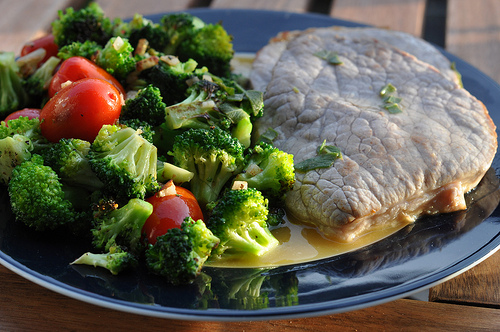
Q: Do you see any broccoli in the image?
A: Yes, there is broccoli.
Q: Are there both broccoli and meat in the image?
A: Yes, there are both broccoli and meat.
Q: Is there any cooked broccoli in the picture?
A: Yes, there is cooked broccoli.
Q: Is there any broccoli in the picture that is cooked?
A: Yes, there is broccoli that is cooked.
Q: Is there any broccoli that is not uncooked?
A: Yes, there is cooked broccoli.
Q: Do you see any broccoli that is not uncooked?
A: Yes, there is cooked broccoli.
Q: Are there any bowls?
A: No, there are no bowls.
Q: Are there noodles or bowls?
A: No, there are no bowls or noodles.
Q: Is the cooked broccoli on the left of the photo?
A: Yes, the broccoli is on the left of the image.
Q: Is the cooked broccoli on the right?
A: No, the broccoli is on the left of the image.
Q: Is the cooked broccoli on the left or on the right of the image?
A: The broccoli is on the left of the image.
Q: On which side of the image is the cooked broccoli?
A: The broccoli is on the left of the image.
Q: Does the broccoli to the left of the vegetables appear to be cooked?
A: Yes, the broccoli is cooked.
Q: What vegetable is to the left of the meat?
A: The vegetable is broccoli.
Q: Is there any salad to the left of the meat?
A: No, there is broccoli to the left of the meat.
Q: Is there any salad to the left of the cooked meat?
A: No, there is broccoli to the left of the meat.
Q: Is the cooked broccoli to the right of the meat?
A: No, the broccoli is to the left of the meat.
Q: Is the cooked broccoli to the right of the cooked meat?
A: No, the broccoli is to the left of the meat.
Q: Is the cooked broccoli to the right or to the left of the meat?
A: The broccoli is to the left of the meat.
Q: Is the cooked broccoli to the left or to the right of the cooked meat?
A: The broccoli is to the left of the meat.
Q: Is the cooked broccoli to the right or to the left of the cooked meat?
A: The broccoli is to the left of the meat.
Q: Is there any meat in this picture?
A: Yes, there is meat.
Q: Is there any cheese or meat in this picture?
A: Yes, there is meat.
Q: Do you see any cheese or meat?
A: Yes, there is meat.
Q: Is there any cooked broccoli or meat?
A: Yes, there is cooked meat.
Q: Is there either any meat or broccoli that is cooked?
A: Yes, the meat is cooked.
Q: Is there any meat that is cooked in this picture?
A: Yes, there is cooked meat.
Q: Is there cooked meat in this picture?
A: Yes, there is cooked meat.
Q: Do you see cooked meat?
A: Yes, there is cooked meat.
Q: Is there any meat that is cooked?
A: Yes, there is meat that is cooked.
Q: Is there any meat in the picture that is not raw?
A: Yes, there is cooked meat.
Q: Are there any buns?
A: No, there are no buns.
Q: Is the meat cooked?
A: Yes, the meat is cooked.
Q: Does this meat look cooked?
A: Yes, the meat is cooked.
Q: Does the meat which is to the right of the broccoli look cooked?
A: Yes, the meat is cooked.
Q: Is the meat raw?
A: No, the meat is cooked.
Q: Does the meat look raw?
A: No, the meat is cooked.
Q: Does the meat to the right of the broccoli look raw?
A: No, the meat is cooked.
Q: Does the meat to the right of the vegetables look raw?
A: No, the meat is cooked.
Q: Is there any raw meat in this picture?
A: No, there is meat but it is cooked.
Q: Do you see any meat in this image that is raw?
A: No, there is meat but it is cooked.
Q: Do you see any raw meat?
A: No, there is meat but it is cooked.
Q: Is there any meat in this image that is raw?
A: No, there is meat but it is cooked.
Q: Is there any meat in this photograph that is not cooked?
A: No, there is meat but it is cooked.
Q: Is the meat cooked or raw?
A: The meat is cooked.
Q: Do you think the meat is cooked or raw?
A: The meat is cooked.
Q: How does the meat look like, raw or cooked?
A: The meat is cooked.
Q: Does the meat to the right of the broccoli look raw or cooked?
A: The meat is cooked.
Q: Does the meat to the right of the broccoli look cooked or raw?
A: The meat is cooked.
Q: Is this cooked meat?
A: Yes, this is cooked meat.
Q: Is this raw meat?
A: No, this is cooked meat.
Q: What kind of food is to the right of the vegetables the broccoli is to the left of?
A: The food is meat.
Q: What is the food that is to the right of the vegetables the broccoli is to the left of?
A: The food is meat.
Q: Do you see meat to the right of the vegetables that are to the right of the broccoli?
A: Yes, there is meat to the right of the vegetables.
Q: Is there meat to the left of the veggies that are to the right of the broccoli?
A: No, the meat is to the right of the veggies.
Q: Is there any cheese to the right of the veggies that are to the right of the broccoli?
A: No, there is meat to the right of the veggies.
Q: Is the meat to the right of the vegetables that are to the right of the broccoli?
A: Yes, the meat is to the right of the veggies.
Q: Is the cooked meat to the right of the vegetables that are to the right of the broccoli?
A: Yes, the meat is to the right of the veggies.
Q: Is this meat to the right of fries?
A: No, the meat is to the right of the veggies.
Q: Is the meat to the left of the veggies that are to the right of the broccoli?
A: No, the meat is to the right of the vegetables.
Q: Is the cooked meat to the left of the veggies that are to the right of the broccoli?
A: No, the meat is to the right of the vegetables.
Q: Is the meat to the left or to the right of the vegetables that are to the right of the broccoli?
A: The meat is to the right of the vegetables.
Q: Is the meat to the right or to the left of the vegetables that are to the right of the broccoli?
A: The meat is to the right of the vegetables.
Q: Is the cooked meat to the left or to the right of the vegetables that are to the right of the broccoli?
A: The meat is to the right of the vegetables.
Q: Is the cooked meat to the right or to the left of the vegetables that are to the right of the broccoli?
A: The meat is to the right of the vegetables.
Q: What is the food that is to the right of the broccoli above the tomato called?
A: The food is meat.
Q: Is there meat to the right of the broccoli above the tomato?
A: Yes, there is meat to the right of the broccoli.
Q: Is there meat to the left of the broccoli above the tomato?
A: No, the meat is to the right of the broccoli.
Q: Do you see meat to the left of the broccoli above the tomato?
A: No, the meat is to the right of the broccoli.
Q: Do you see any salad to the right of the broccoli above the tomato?
A: No, there is meat to the right of the broccoli.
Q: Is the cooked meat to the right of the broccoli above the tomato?
A: Yes, the meat is to the right of the broccoli.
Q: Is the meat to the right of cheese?
A: No, the meat is to the right of the broccoli.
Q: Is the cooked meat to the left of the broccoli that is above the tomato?
A: No, the meat is to the right of the broccoli.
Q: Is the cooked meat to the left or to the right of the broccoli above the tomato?
A: The meat is to the right of the broccoli.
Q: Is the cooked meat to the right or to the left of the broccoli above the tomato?
A: The meat is to the right of the broccoli.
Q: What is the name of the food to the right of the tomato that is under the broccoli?
A: The food is meat.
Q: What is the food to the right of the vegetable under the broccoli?
A: The food is meat.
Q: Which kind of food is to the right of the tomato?
A: The food is meat.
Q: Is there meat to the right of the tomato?
A: Yes, there is meat to the right of the tomato.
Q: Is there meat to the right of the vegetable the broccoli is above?
A: Yes, there is meat to the right of the tomato.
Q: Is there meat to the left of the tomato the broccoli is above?
A: No, the meat is to the right of the tomato.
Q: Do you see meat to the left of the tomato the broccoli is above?
A: No, the meat is to the right of the tomato.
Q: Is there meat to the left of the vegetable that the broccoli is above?
A: No, the meat is to the right of the tomato.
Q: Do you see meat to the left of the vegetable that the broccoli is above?
A: No, the meat is to the right of the tomato.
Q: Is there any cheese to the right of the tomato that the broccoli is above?
A: No, there is meat to the right of the tomato.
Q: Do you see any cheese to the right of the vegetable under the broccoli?
A: No, there is meat to the right of the tomato.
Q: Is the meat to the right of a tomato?
A: Yes, the meat is to the right of a tomato.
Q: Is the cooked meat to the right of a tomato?
A: Yes, the meat is to the right of a tomato.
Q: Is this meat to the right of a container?
A: No, the meat is to the right of a tomato.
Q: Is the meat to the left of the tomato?
A: No, the meat is to the right of the tomato.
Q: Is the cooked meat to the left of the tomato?
A: No, the meat is to the right of the tomato.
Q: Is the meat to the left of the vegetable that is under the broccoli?
A: No, the meat is to the right of the tomato.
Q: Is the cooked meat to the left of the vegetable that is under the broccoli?
A: No, the meat is to the right of the tomato.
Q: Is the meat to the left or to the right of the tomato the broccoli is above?
A: The meat is to the right of the tomato.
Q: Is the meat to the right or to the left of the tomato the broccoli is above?
A: The meat is to the right of the tomato.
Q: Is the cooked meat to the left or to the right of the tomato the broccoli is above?
A: The meat is to the right of the tomato.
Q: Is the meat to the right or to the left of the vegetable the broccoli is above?
A: The meat is to the right of the tomato.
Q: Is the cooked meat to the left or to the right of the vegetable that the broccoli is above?
A: The meat is to the right of the tomato.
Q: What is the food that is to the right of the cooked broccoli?
A: The food is meat.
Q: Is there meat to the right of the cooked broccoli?
A: Yes, there is meat to the right of the broccoli.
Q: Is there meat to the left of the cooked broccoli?
A: No, the meat is to the right of the broccoli.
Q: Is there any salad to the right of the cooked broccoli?
A: No, there is meat to the right of the broccoli.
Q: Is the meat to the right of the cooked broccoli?
A: Yes, the meat is to the right of the broccoli.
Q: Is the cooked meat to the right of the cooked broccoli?
A: Yes, the meat is to the right of the broccoli.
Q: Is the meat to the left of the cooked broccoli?
A: No, the meat is to the right of the broccoli.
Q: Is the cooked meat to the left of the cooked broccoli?
A: No, the meat is to the right of the broccoli.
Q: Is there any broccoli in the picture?
A: Yes, there is broccoli.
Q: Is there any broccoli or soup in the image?
A: Yes, there is broccoli.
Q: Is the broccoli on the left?
A: Yes, the broccoli is on the left of the image.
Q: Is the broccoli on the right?
A: No, the broccoli is on the left of the image.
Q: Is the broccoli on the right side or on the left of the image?
A: The broccoli is on the left of the image.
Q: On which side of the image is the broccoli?
A: The broccoli is on the left of the image.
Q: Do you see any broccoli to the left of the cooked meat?
A: Yes, there is broccoli to the left of the meat.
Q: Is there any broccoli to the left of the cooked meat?
A: Yes, there is broccoli to the left of the meat.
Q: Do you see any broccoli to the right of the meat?
A: No, the broccoli is to the left of the meat.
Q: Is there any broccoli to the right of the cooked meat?
A: No, the broccoli is to the left of the meat.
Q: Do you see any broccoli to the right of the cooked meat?
A: No, the broccoli is to the left of the meat.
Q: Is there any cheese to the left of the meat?
A: No, there is broccoli to the left of the meat.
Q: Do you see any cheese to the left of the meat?
A: No, there is broccoli to the left of the meat.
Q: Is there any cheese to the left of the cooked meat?
A: No, there is broccoli to the left of the meat.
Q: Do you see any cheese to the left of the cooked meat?
A: No, there is broccoli to the left of the meat.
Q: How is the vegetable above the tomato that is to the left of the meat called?
A: The vegetable is broccoli.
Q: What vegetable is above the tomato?
A: The vegetable is broccoli.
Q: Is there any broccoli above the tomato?
A: Yes, there is broccoli above the tomato.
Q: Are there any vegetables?
A: Yes, there are vegetables.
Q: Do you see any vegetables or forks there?
A: Yes, there are vegetables.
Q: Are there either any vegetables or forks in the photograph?
A: Yes, there are vegetables.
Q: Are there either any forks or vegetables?
A: Yes, there are vegetables.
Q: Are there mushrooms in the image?
A: No, there are no mushrooms.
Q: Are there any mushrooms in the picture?
A: No, there are no mushrooms.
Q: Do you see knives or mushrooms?
A: No, there are no mushrooms or knives.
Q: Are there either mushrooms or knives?
A: No, there are no mushrooms or knives.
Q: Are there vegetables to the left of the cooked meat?
A: Yes, there are vegetables to the left of the meat.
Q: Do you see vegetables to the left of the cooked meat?
A: Yes, there are vegetables to the left of the meat.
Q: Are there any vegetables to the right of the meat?
A: No, the vegetables are to the left of the meat.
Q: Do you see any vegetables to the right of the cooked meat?
A: No, the vegetables are to the left of the meat.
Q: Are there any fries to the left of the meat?
A: No, there are vegetables to the left of the meat.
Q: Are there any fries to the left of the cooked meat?
A: No, there are vegetables to the left of the meat.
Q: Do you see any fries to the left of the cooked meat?
A: No, there are vegetables to the left of the meat.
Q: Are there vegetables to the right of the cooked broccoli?
A: Yes, there are vegetables to the right of the broccoli.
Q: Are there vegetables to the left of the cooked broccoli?
A: No, the vegetables are to the right of the broccoli.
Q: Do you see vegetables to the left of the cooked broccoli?
A: No, the vegetables are to the right of the broccoli.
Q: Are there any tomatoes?
A: Yes, there is a tomato.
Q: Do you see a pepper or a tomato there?
A: Yes, there is a tomato.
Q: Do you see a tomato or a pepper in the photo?
A: Yes, there is a tomato.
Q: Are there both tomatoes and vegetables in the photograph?
A: Yes, there are both a tomato and a vegetable.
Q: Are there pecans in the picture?
A: No, there are no pecans.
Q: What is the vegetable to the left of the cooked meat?
A: The vegetable is a tomato.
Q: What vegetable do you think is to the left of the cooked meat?
A: The vegetable is a tomato.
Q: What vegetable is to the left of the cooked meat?
A: The vegetable is a tomato.